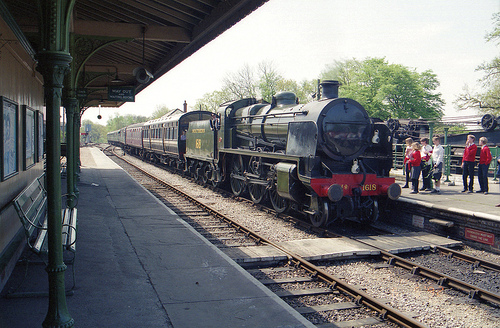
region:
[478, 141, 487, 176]
Person wearing red shirt.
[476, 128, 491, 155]
Person has blonde hair.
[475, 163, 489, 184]
Person wearing black pants.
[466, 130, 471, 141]
Person has blonde hair.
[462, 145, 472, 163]
Person wearing red shirt.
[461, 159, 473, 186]
Person wearing black pants.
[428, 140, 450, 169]
Person wearing white shirt.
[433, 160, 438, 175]
Person wearing dark shorts.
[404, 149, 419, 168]
Person wearing red shirt.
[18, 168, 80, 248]
Park bench in between poles.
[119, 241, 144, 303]
shade on the platform.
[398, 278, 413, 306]
pebbles between the tracks.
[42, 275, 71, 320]
pole on the platform.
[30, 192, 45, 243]
bench on the platform.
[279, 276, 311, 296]
wood slats between tracks.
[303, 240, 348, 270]
walkway between the tracks.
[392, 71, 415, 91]
leaves on the tree.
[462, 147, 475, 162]
red shirt on man.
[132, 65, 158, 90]
light on the platform.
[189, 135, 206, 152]
number on the train.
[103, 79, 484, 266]
a train at a station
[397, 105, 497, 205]
people waiting to board a train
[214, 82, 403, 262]
the engine is black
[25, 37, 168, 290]
a train station near the tracks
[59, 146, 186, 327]
a platform at the station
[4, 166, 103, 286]
a bench on the platform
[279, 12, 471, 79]
a gray sky above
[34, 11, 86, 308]
a green pole at the station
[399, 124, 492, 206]
three people are wearing red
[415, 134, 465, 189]
two people wearing white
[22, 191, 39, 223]
back of the bench.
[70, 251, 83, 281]
leg of the bench.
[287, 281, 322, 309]
wooden slats between tracks.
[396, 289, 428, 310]
pebbles between the tracks.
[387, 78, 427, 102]
leaves on the trees.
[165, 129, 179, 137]
windows on the train.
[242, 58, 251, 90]
limbs on the tree.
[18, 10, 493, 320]
A train sitting at a train depot.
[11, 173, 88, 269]
A bench sitting against the building.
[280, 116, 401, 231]
A section of the train engine is red.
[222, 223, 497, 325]
Two sets of train tracks.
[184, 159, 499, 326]
Gravel around the train tracks.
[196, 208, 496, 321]
Crossties under the train track rails.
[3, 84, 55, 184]
Framed posters on the building.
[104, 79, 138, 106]
A square sign hanging from the roof of the building.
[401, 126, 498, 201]
A group of people waiting to get on the train.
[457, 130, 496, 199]
Two people in red shirts and dark pants.